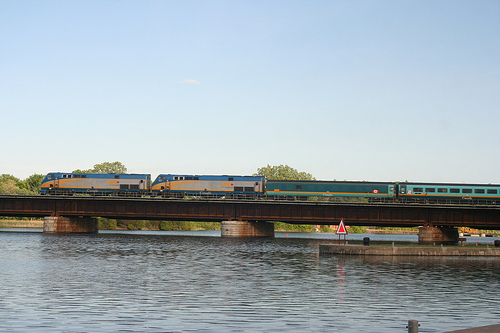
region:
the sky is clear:
[22, 41, 59, 101]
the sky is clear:
[78, 58, 318, 137]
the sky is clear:
[209, 44, 368, 124]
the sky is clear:
[18, 18, 121, 74]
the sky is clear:
[88, 32, 353, 168]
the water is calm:
[49, 241, 174, 313]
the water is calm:
[188, 265, 307, 321]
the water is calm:
[258, 229, 345, 304]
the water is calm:
[112, 240, 211, 301]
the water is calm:
[128, 251, 268, 321]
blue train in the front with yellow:
[25, 152, 110, 202]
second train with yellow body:
[155, 183, 244, 256]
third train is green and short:
[300, 182, 353, 212]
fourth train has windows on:
[425, 175, 461, 210]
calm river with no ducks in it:
[100, 235, 297, 332]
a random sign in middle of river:
[307, 212, 362, 252]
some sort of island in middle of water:
[423, 246, 467, 275]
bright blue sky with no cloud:
[166, 19, 292, 86]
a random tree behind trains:
[255, 133, 361, 178]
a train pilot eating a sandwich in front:
[48, 164, 111, 194]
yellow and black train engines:
[34, 175, 270, 205]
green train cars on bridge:
[257, 170, 484, 202]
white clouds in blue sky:
[21, 11, 85, 53]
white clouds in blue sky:
[33, 95, 98, 132]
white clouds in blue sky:
[98, 29, 156, 93]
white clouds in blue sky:
[121, 73, 176, 116]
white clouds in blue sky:
[188, 23, 239, 67]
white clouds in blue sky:
[188, 86, 232, 126]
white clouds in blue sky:
[284, 18, 365, 102]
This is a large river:
[112, 246, 302, 316]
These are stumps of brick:
[56, 206, 338, 248]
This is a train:
[34, 169, 337, 241]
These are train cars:
[206, 171, 458, 205]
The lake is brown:
[159, 269, 219, 324]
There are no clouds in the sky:
[170, 89, 270, 135]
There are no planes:
[173, 117, 270, 157]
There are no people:
[83, 244, 154, 325]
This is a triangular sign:
[317, 204, 373, 250]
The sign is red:
[312, 216, 408, 224]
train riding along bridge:
[3, 158, 497, 260]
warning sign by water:
[331, 213, 348, 249]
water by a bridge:
[38, 252, 270, 300]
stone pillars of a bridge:
[215, 217, 275, 247]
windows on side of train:
[407, 182, 498, 199]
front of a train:
[33, 168, 60, 200]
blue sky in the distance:
[28, 39, 435, 126]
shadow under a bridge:
[105, 220, 216, 256]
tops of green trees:
[6, 171, 37, 197]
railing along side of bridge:
[11, 188, 173, 198]